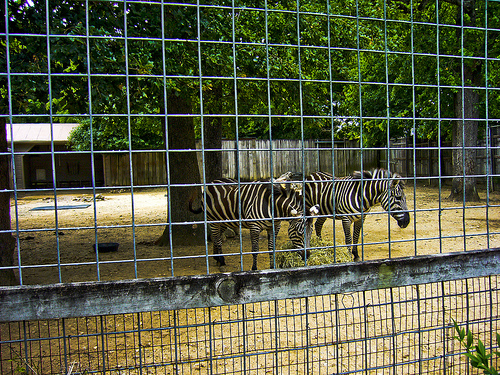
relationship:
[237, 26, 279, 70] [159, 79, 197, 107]
leaves on a branch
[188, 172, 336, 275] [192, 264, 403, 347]
zebra on a ground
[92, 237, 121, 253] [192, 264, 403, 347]
container on ground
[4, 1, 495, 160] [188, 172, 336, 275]
fence behind zebra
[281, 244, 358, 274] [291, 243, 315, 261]
grass for feeding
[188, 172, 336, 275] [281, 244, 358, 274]
zebra feeding on grass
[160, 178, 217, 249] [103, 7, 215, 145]
trunk of a tree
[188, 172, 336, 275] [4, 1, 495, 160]
zebra are standing behind fence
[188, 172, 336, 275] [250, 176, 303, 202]
zebra has short hair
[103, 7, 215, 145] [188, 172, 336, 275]
tree behind zebra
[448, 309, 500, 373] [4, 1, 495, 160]
plant outside fence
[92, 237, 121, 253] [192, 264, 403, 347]
bowl on ground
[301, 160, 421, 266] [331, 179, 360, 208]
zebra has black stripes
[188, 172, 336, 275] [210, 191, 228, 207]
zebra has white stripes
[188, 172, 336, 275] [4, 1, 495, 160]
zebra inside fence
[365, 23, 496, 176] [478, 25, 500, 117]
trees in corner